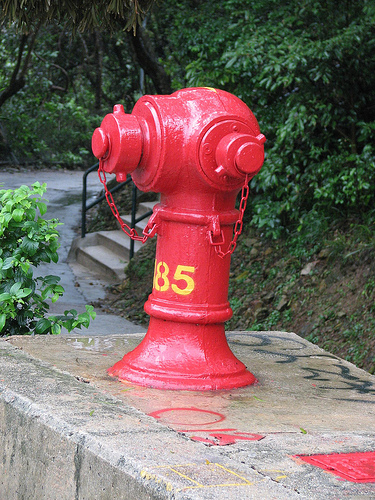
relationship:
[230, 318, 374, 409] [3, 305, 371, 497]
graffiti on platform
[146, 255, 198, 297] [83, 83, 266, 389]
yellow paint on fire hydrant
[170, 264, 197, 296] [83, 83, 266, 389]
number on fire hydrant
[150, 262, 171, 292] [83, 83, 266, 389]
number on fire hydrant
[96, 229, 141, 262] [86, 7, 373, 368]
concrete stair goes past bushes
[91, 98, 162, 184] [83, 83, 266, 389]
stopper on fire hydrant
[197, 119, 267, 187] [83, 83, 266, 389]
stopper on fire hydrant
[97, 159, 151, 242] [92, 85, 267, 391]
chain on fire hydrant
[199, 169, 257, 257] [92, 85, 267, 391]
chain on fire hydrant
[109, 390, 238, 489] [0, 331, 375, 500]
crack in cement